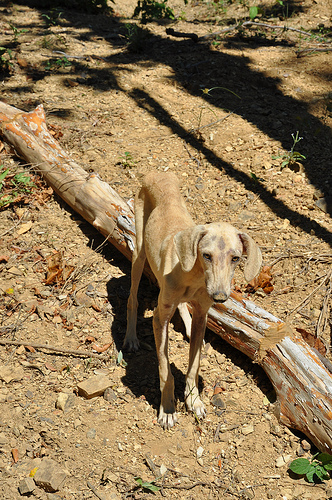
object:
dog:
[121, 172, 264, 431]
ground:
[0, 0, 331, 499]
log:
[0, 101, 331, 455]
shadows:
[19, 50, 331, 248]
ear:
[169, 225, 209, 272]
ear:
[239, 233, 262, 281]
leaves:
[288, 455, 313, 477]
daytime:
[0, 0, 331, 500]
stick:
[0, 338, 109, 362]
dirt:
[212, 291, 227, 301]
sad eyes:
[202, 252, 214, 262]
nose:
[212, 292, 228, 302]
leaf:
[134, 478, 160, 493]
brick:
[75, 374, 116, 398]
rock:
[241, 425, 253, 434]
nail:
[161, 424, 166, 432]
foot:
[157, 401, 179, 431]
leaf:
[159, 462, 167, 477]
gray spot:
[217, 235, 226, 251]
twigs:
[279, 271, 331, 313]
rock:
[18, 477, 37, 495]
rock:
[103, 387, 119, 402]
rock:
[215, 353, 225, 363]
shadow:
[104, 273, 203, 413]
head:
[174, 222, 262, 304]